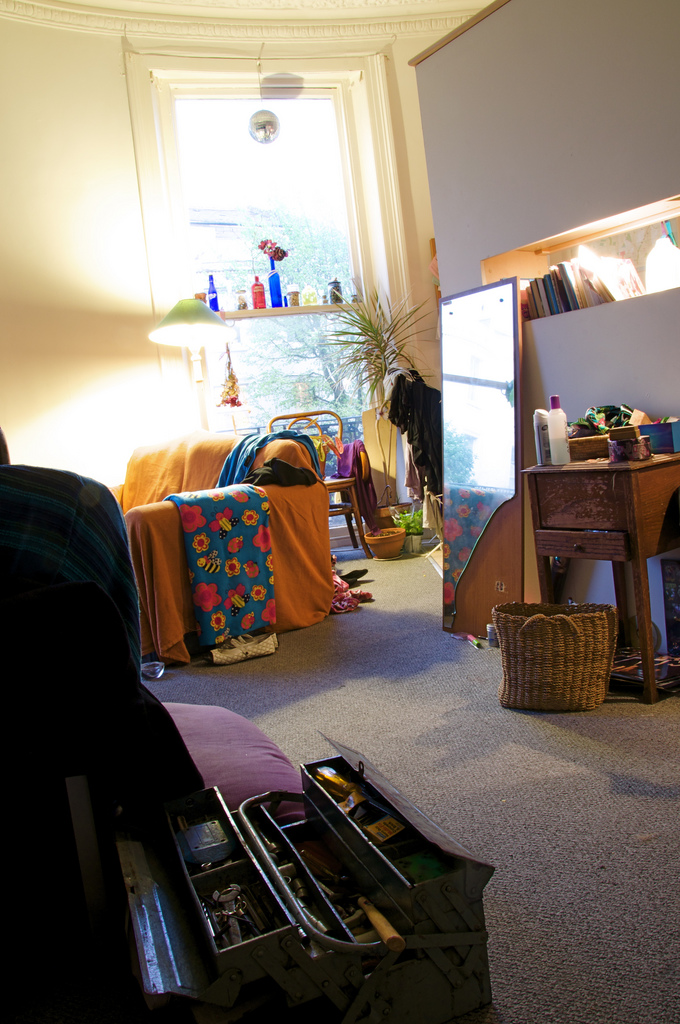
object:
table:
[520, 449, 679, 704]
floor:
[0, 0, 680, 865]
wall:
[408, 29, 680, 656]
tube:
[468, 633, 482, 649]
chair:
[268, 410, 373, 560]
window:
[150, 69, 384, 549]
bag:
[491, 600, 619, 710]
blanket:
[160, 484, 276, 646]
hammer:
[328, 874, 405, 950]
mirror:
[439, 276, 525, 638]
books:
[521, 258, 645, 323]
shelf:
[479, 191, 679, 322]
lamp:
[148, 298, 241, 352]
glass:
[205, 310, 367, 529]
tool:
[300, 849, 347, 888]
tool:
[315, 766, 406, 824]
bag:
[116, 728, 497, 1024]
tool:
[277, 862, 296, 876]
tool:
[276, 862, 307, 898]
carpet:
[139, 545, 680, 1022]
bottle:
[532, 395, 569, 466]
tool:
[213, 884, 242, 945]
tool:
[337, 791, 405, 845]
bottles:
[195, 255, 358, 312]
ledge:
[155, 299, 365, 323]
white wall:
[412, 6, 680, 657]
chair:
[108, 429, 333, 668]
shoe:
[210, 633, 280, 666]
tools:
[166, 755, 467, 955]